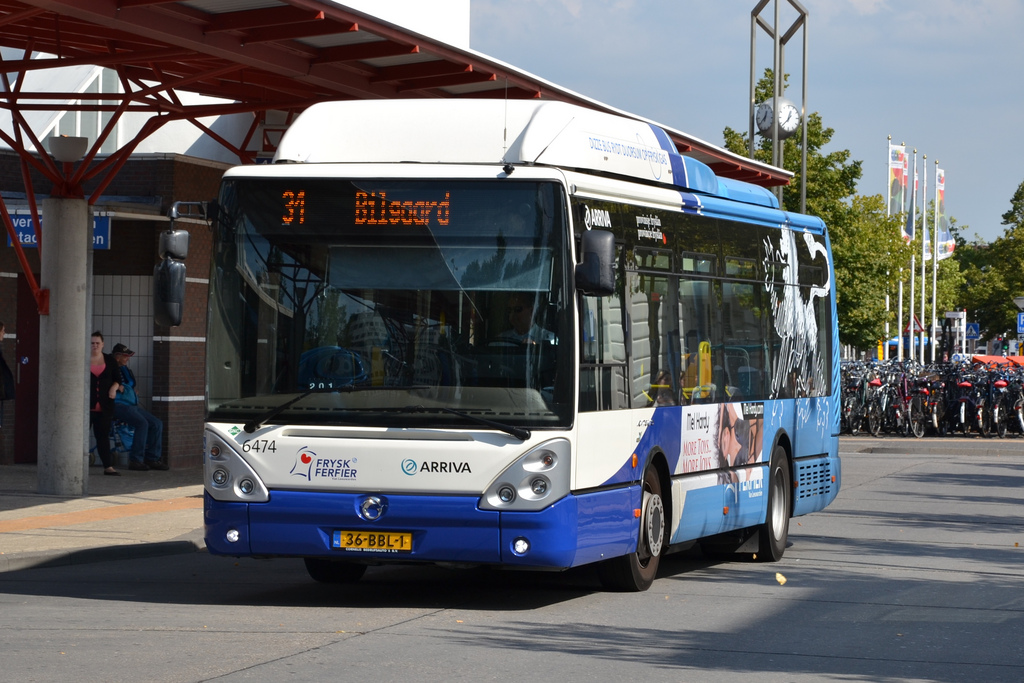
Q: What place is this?
A: It is a road.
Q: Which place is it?
A: It is a road.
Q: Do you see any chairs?
A: No, there are no chairs.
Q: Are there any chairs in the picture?
A: No, there are no chairs.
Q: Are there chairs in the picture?
A: No, there are no chairs.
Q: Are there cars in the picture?
A: No, there are no cars.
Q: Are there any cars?
A: No, there are no cars.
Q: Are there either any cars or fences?
A: No, there are no cars or fences.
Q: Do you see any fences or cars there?
A: No, there are no cars or fences.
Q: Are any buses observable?
A: Yes, there is a bus.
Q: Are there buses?
A: Yes, there is a bus.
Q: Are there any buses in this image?
A: Yes, there is a bus.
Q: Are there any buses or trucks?
A: Yes, there is a bus.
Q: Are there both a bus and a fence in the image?
A: No, there is a bus but no fences.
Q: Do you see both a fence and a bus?
A: No, there is a bus but no fences.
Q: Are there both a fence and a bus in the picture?
A: No, there is a bus but no fences.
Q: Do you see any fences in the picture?
A: No, there are no fences.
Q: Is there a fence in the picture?
A: No, there are no fences.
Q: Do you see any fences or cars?
A: No, there are no fences or cars.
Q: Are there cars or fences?
A: No, there are no fences or cars.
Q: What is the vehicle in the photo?
A: The vehicle is a bus.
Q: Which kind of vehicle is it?
A: The vehicle is a bus.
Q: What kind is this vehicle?
A: This is a bus.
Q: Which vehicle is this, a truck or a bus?
A: This is a bus.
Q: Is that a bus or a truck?
A: That is a bus.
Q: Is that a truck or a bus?
A: That is a bus.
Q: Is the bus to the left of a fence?
A: No, the bus is to the left of a motorcycle.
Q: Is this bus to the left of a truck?
A: No, the bus is to the left of a motorcycle.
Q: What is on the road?
A: The bus is on the road.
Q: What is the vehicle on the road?
A: The vehicle is a bus.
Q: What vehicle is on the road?
A: The vehicle is a bus.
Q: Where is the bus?
A: The bus is on the road.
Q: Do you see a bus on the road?
A: Yes, there is a bus on the road.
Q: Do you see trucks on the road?
A: No, there is a bus on the road.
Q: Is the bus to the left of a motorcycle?
A: Yes, the bus is to the left of a motorcycle.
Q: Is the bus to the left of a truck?
A: No, the bus is to the left of a motorcycle.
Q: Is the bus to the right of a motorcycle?
A: No, the bus is to the left of a motorcycle.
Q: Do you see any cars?
A: No, there are no cars.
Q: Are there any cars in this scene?
A: No, there are no cars.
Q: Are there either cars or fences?
A: No, there are no cars or fences.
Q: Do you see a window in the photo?
A: Yes, there is a window.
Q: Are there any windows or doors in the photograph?
A: Yes, there is a window.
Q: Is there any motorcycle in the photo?
A: Yes, there is a motorcycle.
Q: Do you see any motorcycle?
A: Yes, there is a motorcycle.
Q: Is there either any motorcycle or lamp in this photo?
A: Yes, there is a motorcycle.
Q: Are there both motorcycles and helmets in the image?
A: No, there is a motorcycle but no helmets.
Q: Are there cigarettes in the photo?
A: No, there are no cigarettes.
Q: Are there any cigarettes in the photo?
A: No, there are no cigarettes.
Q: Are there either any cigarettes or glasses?
A: No, there are no cigarettes or glasses.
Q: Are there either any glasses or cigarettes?
A: No, there are no cigarettes or glasses.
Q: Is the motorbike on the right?
A: Yes, the motorbike is on the right of the image.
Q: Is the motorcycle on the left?
A: No, the motorcycle is on the right of the image.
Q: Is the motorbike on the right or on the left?
A: The motorbike is on the right of the image.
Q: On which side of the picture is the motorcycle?
A: The motorcycle is on the right of the image.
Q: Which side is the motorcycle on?
A: The motorcycle is on the right of the image.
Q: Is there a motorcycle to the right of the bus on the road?
A: Yes, there is a motorcycle to the right of the bus.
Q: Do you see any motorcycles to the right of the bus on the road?
A: Yes, there is a motorcycle to the right of the bus.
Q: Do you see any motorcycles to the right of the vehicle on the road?
A: Yes, there is a motorcycle to the right of the bus.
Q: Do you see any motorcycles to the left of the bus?
A: No, the motorcycle is to the right of the bus.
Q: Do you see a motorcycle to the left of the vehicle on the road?
A: No, the motorcycle is to the right of the bus.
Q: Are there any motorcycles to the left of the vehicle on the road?
A: No, the motorcycle is to the right of the bus.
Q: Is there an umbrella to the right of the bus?
A: No, there is a motorcycle to the right of the bus.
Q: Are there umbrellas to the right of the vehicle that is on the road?
A: No, there is a motorcycle to the right of the bus.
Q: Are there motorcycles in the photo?
A: Yes, there is a motorcycle.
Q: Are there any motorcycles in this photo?
A: Yes, there is a motorcycle.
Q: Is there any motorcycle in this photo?
A: Yes, there is a motorcycle.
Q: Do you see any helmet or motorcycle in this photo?
A: Yes, there is a motorcycle.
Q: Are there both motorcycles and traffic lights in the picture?
A: No, there is a motorcycle but no traffic lights.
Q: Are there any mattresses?
A: No, there are no mattresses.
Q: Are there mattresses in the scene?
A: No, there are no mattresses.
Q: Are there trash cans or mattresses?
A: No, there are no mattresses or trash cans.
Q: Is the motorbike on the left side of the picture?
A: No, the motorbike is on the right of the image.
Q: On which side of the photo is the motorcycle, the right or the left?
A: The motorcycle is on the right of the image.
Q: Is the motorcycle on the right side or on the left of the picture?
A: The motorcycle is on the right of the image.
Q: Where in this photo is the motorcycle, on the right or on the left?
A: The motorcycle is on the right of the image.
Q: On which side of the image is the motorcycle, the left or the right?
A: The motorcycle is on the right of the image.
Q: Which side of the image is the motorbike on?
A: The motorbike is on the right of the image.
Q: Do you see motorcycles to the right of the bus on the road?
A: Yes, there is a motorcycle to the right of the bus.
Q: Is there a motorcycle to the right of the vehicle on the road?
A: Yes, there is a motorcycle to the right of the bus.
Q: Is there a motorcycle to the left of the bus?
A: No, the motorcycle is to the right of the bus.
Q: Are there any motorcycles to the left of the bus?
A: No, the motorcycle is to the right of the bus.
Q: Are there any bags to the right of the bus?
A: No, there is a motorcycle to the right of the bus.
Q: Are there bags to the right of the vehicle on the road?
A: No, there is a motorcycle to the right of the bus.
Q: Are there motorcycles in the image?
A: Yes, there is a motorcycle.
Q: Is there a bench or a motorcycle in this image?
A: Yes, there is a motorcycle.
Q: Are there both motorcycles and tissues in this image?
A: No, there is a motorcycle but no tissues.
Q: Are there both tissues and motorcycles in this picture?
A: No, there is a motorcycle but no tissues.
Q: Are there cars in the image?
A: No, there are no cars.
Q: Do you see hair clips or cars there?
A: No, there are no cars or hair clips.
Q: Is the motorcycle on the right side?
A: Yes, the motorcycle is on the right of the image.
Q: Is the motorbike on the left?
A: No, the motorbike is on the right of the image.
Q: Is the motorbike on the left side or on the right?
A: The motorbike is on the right of the image.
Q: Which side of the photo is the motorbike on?
A: The motorbike is on the right of the image.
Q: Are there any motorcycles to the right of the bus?
A: Yes, there is a motorcycle to the right of the bus.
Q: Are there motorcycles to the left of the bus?
A: No, the motorcycle is to the right of the bus.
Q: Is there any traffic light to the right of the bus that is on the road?
A: No, there is a motorcycle to the right of the bus.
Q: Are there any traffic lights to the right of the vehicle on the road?
A: No, there is a motorcycle to the right of the bus.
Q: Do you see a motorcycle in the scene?
A: Yes, there is a motorcycle.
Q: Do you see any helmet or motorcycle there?
A: Yes, there is a motorcycle.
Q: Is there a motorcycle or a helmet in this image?
A: Yes, there is a motorcycle.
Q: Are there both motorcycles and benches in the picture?
A: No, there is a motorcycle but no benches.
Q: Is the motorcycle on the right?
A: Yes, the motorcycle is on the right of the image.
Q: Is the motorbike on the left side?
A: No, the motorbike is on the right of the image.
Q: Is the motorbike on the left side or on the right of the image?
A: The motorbike is on the right of the image.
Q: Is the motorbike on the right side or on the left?
A: The motorbike is on the right of the image.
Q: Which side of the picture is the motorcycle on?
A: The motorcycle is on the right of the image.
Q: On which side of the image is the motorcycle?
A: The motorcycle is on the right of the image.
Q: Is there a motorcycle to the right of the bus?
A: Yes, there is a motorcycle to the right of the bus.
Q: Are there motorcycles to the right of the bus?
A: Yes, there is a motorcycle to the right of the bus.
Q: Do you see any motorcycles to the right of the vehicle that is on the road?
A: Yes, there is a motorcycle to the right of the bus.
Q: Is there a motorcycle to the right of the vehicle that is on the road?
A: Yes, there is a motorcycle to the right of the bus.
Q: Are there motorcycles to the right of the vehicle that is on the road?
A: Yes, there is a motorcycle to the right of the bus.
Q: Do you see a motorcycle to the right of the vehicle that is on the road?
A: Yes, there is a motorcycle to the right of the bus.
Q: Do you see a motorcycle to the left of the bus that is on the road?
A: No, the motorcycle is to the right of the bus.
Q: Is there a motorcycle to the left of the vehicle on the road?
A: No, the motorcycle is to the right of the bus.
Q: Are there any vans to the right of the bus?
A: No, there is a motorcycle to the right of the bus.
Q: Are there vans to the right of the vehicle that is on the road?
A: No, there is a motorcycle to the right of the bus.